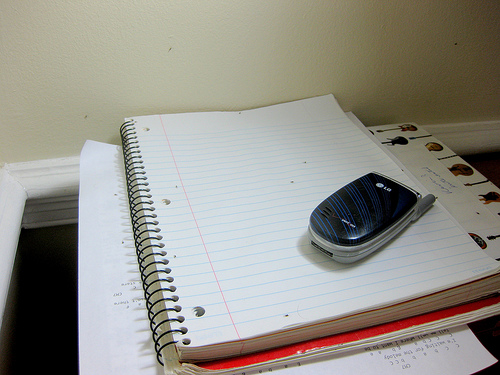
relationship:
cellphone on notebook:
[314, 166, 416, 253] [114, 110, 472, 341]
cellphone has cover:
[314, 166, 416, 253] [320, 195, 388, 216]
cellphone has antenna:
[314, 166, 416, 253] [421, 188, 437, 214]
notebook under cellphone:
[114, 110, 472, 341] [314, 166, 416, 253]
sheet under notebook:
[78, 151, 146, 363] [114, 110, 472, 341]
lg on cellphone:
[383, 181, 404, 194] [314, 166, 416, 253]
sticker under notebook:
[400, 116, 493, 260] [114, 110, 472, 341]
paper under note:
[59, 148, 154, 375] [114, 110, 472, 341]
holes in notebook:
[147, 118, 169, 226] [114, 110, 472, 341]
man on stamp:
[468, 229, 485, 259] [467, 215, 500, 275]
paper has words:
[59, 148, 154, 375] [119, 232, 145, 310]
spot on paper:
[83, 346, 99, 375] [59, 148, 154, 375]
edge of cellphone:
[314, 237, 343, 257] [314, 166, 416, 253]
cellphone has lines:
[314, 166, 416, 253] [344, 191, 380, 220]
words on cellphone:
[333, 217, 359, 236] [314, 166, 416, 253]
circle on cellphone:
[377, 178, 387, 189] [314, 166, 416, 253]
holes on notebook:
[147, 118, 169, 226] [114, 110, 472, 341]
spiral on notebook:
[113, 126, 157, 283] [114, 110, 472, 341]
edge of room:
[407, 120, 500, 156] [34, 23, 496, 296]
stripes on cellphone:
[334, 202, 390, 233] [314, 166, 416, 253]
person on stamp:
[387, 129, 416, 149] [467, 215, 500, 275]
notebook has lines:
[114, 110, 472, 341] [206, 149, 378, 181]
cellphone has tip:
[314, 166, 416, 253] [420, 187, 443, 205]